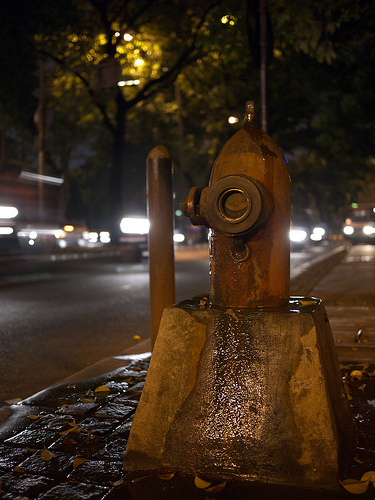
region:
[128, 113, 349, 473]
rusted fire hydrant on cement block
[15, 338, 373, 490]
wet pavement around cement block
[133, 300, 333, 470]
water dripping down cement block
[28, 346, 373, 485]
yellow leaves on sidewalk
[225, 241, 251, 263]
metal ring hanging from fire hydrant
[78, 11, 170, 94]
lights coming through tree branches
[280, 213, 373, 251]
headlights of cars on highway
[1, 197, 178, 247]
lighted signs from businesses across the street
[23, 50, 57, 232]
backs of several street signs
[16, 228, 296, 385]
street beside fire hydrant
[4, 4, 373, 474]
scene takes place at night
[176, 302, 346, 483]
the structure is wet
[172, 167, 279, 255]
metal pieces are gray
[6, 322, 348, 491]
leaves on the ground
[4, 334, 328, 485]
the ground is wet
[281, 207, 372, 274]
cars driving in the road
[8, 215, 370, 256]
cars' lights are on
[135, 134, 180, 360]
metal pole behind hydrant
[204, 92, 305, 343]
the hydrant is red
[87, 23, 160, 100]
street lights showing through tree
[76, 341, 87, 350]
part of a road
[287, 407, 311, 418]
side of a rock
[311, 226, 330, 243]
part of a light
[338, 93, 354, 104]
part of a tree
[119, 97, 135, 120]
part of a branch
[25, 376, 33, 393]
edge of a road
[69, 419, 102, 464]
edge of a path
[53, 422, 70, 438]
part of a road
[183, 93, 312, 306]
rusted fire hydrant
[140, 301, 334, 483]
water leaking on to base of fire hydrant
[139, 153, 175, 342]
pole next to fire hydrant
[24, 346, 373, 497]
wet sidewalk surrounding fire hydrant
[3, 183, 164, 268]
lights from businesses in background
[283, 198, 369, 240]
head lights of cars coming down road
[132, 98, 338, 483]
fire hydrant sitting on cement base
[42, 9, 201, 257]
tree in front of business signs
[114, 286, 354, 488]
cement block on the street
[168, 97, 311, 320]
fire hydrant on top of cement block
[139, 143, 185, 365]
metal pole near street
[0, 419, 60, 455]
brick in the sidewalk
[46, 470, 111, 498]
brick in the sidewalk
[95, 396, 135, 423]
brick in the sidewalk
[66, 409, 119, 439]
brick in the sidewalk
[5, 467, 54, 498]
brick in the sidewalk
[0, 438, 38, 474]
brick in the sidewalk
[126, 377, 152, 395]
brick in the sidewalk